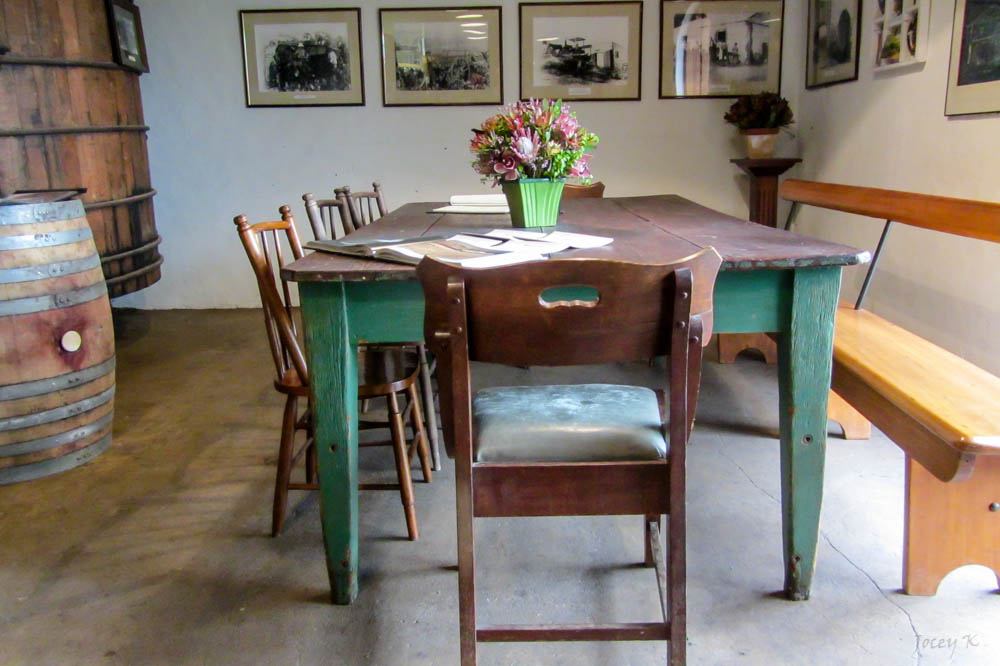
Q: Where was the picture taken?
A: In an eclectically designed dining room of a home.